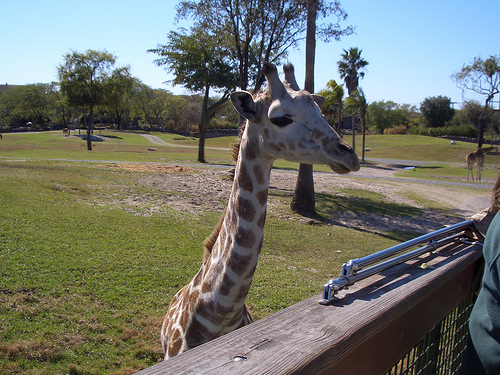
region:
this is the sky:
[59, 7, 89, 24]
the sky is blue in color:
[87, 0, 134, 26]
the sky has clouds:
[376, 83, 408, 97]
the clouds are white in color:
[366, 77, 395, 92]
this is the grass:
[55, 224, 140, 264]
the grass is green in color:
[28, 222, 124, 264]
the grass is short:
[20, 220, 142, 288]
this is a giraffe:
[158, 61, 360, 361]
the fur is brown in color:
[227, 207, 261, 227]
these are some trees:
[166, 11, 333, 62]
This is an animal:
[172, 83, 424, 353]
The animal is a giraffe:
[94, 152, 311, 370]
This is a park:
[64, 219, 181, 286]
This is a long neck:
[237, 115, 262, 308]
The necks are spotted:
[205, 232, 275, 357]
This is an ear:
[205, 59, 319, 208]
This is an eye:
[274, 102, 296, 140]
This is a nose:
[302, 125, 372, 169]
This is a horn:
[234, 55, 296, 105]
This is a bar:
[305, 274, 451, 332]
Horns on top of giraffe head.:
[264, 62, 303, 92]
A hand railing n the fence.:
[326, 207, 486, 249]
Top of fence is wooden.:
[277, 276, 456, 360]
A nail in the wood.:
[219, 333, 261, 363]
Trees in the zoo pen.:
[36, 52, 220, 164]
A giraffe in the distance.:
[447, 125, 497, 180]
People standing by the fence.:
[461, 170, 498, 334]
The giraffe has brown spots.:
[216, 194, 257, 316]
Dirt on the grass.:
[128, 161, 234, 219]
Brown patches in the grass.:
[21, 283, 84, 373]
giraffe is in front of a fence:
[159, 60, 360, 360]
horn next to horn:
[263, 61, 285, 95]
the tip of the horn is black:
[263, 62, 276, 72]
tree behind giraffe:
[57, 48, 134, 151]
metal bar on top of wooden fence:
[322, 215, 483, 304]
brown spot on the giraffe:
[231, 195, 256, 221]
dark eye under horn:
[271, 116, 293, 126]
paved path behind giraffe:
[128, 128, 242, 150]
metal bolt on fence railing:
[235, 355, 248, 360]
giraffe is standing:
[161, 60, 358, 357]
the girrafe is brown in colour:
[169, 47, 380, 290]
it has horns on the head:
[203, 58, 315, 114]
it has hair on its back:
[193, 114, 236, 265]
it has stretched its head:
[215, 40, 404, 296]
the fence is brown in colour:
[226, 325, 335, 372]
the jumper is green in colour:
[474, 240, 499, 339]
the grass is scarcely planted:
[11, 124, 173, 321]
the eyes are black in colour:
[238, 103, 305, 138]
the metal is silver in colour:
[290, 241, 464, 305]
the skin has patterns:
[226, 73, 383, 183]